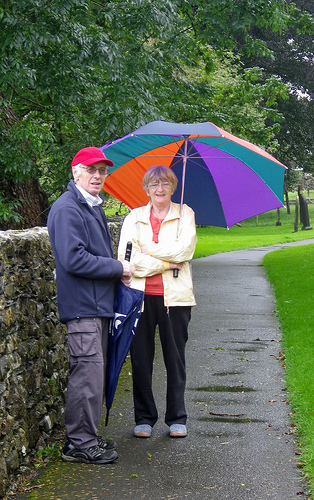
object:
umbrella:
[95, 118, 289, 231]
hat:
[71, 145, 115, 172]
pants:
[65, 318, 106, 450]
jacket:
[46, 182, 124, 325]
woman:
[116, 163, 200, 441]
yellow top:
[116, 198, 199, 310]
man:
[40, 143, 135, 471]